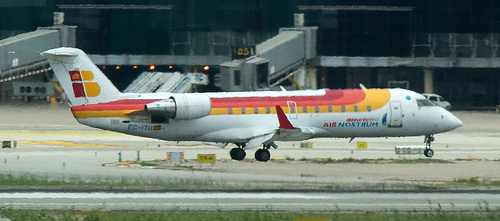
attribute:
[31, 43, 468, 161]
plane — white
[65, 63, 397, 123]
decorations — red, yellow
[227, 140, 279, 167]
back wheels — black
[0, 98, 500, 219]
ground — grey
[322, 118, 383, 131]
air nostrom — red, blue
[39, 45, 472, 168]
airplane — red, white, yellow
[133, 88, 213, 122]
engine — white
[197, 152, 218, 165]
sign — yellow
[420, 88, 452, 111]
car — white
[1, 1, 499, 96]
building — grey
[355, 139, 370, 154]
sign — yellow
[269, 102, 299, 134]
wing tip — red